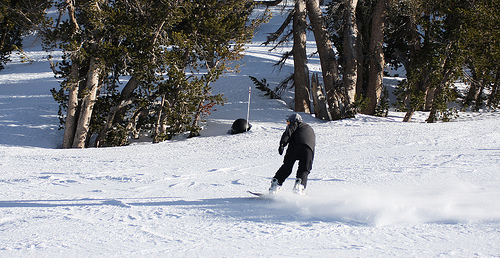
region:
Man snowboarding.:
[262, 102, 333, 214]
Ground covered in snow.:
[15, 135, 218, 217]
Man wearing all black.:
[258, 101, 338, 202]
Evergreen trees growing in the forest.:
[35, 1, 252, 148]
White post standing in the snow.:
[241, 76, 258, 134]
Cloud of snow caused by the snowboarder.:
[320, 171, 480, 241]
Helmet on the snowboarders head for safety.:
[277, 107, 307, 125]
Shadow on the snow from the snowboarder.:
[0, 180, 252, 217]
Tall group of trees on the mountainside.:
[287, 0, 392, 123]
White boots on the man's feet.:
[260, 169, 312, 203]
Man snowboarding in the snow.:
[226, 108, 355, 216]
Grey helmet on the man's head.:
[277, 109, 305, 126]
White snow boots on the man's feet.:
[262, 169, 310, 200]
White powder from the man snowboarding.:
[287, 177, 497, 236]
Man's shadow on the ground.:
[20, 191, 263, 216]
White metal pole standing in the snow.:
[239, 82, 260, 138]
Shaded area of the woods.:
[4, 4, 239, 151]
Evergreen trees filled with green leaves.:
[297, 1, 497, 118]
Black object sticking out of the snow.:
[227, 114, 254, 138]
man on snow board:
[268, 99, 323, 201]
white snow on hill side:
[80, 178, 122, 213]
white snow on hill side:
[134, 209, 184, 241]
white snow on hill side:
[44, 188, 85, 226]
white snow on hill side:
[438, 135, 466, 179]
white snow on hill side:
[374, 156, 405, 193]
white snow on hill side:
[400, 172, 442, 229]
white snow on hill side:
[342, 145, 383, 182]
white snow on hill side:
[151, 151, 188, 176]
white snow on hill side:
[97, 188, 152, 230]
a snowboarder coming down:
[203, 79, 407, 219]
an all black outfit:
[252, 94, 334, 211]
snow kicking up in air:
[284, 180, 498, 240]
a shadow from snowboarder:
[12, 179, 289, 229]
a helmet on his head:
[271, 107, 301, 126]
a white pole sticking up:
[239, 79, 260, 141]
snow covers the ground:
[26, 0, 495, 257]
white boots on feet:
[246, 172, 343, 216]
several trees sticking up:
[48, 12, 488, 141]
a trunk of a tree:
[352, 0, 384, 121]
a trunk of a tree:
[285, 2, 310, 112]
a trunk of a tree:
[315, 6, 350, 116]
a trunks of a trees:
[55, 47, 100, 147]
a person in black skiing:
[250, 106, 341, 216]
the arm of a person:
[275, 120, 291, 152]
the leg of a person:
[290, 156, 310, 196]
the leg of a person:
[265, 155, 295, 195]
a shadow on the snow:
[2, 192, 260, 210]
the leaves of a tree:
[175, 5, 217, 40]